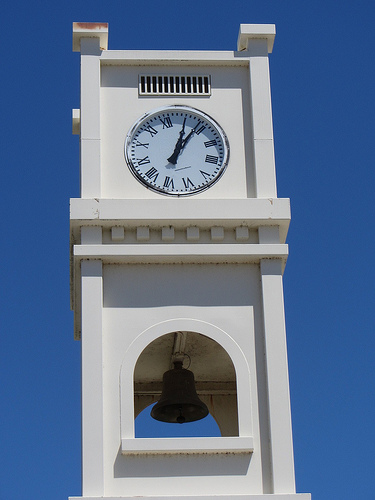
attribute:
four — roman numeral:
[200, 153, 226, 166]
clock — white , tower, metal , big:
[123, 101, 232, 197]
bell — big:
[149, 360, 210, 424]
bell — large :
[142, 356, 219, 426]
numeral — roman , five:
[200, 169, 210, 180]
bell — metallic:
[149, 364, 209, 422]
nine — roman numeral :
[131, 152, 154, 166]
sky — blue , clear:
[1, 1, 373, 499]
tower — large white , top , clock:
[54, 19, 322, 498]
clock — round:
[139, 91, 245, 226]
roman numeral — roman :
[159, 114, 174, 129]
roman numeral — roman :
[142, 123, 159, 136]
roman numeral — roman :
[132, 137, 148, 149]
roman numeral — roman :
[134, 154, 151, 166]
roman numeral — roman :
[146, 167, 158, 182]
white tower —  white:
[176, 268, 255, 328]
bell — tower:
[114, 340, 235, 423]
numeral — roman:
[180, 110, 190, 132]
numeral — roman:
[202, 134, 223, 151]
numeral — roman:
[132, 142, 153, 148]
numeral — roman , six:
[178, 171, 196, 195]